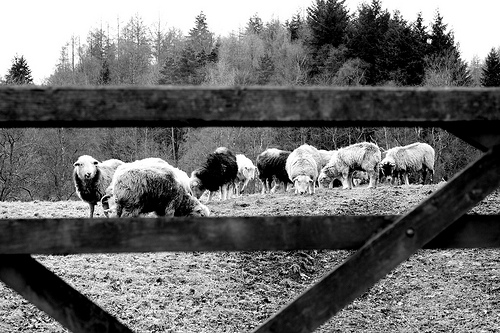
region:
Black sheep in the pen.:
[195, 147, 242, 199]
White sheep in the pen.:
[287, 144, 321, 199]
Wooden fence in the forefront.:
[2, 81, 494, 331]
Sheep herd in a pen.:
[39, 125, 437, 204]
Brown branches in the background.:
[3, 136, 69, 201]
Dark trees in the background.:
[302, 1, 457, 92]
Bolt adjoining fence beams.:
[401, 225, 411, 236]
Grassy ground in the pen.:
[1, 198, 496, 329]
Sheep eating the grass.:
[320, 135, 385, 190]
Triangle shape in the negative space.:
[26, 240, 358, 332]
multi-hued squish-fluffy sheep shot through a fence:
[68, 127, 446, 217]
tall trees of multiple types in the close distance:
[1, 0, 498, 202]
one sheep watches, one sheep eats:
[62, 150, 214, 213]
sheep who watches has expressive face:
[66, 151, 103, 185]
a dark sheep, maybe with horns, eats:
[184, 147, 244, 204]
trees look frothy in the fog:
[63, 27, 451, 160]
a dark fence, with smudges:
[1, 85, 497, 331]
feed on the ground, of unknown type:
[0, 183, 441, 331]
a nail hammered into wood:
[401, 220, 426, 242]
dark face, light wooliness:
[376, 158, 401, 186]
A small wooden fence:
[0, 85, 496, 332]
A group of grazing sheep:
[70, 140, 438, 216]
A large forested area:
[0, 0, 498, 199]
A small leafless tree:
[1, 133, 41, 198]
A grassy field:
[1, 183, 495, 328]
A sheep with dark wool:
[189, 152, 243, 198]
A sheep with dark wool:
[256, 152, 288, 192]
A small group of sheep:
[70, 150, 207, 220]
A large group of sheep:
[185, 140, 436, 195]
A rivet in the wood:
[405, 225, 415, 237]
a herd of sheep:
[69, 132, 459, 232]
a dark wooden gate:
[8, 70, 494, 321]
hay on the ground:
[243, 185, 384, 212]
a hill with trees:
[35, 0, 457, 183]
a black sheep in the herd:
[193, 143, 244, 195]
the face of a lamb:
[381, 158, 397, 188]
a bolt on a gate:
[386, 225, 422, 250]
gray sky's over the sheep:
[20, 0, 261, 53]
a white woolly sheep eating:
[283, 145, 319, 195]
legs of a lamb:
[339, 171, 356, 191]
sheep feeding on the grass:
[245, 138, 436, 195]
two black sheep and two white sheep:
[180, 135, 313, 206]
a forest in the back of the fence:
[4, 54, 262, 141]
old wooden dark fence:
[317, 72, 497, 274]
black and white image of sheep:
[56, 134, 216, 229]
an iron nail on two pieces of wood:
[374, 194, 456, 276]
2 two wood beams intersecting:
[346, 187, 485, 307]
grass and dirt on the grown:
[105, 262, 265, 315]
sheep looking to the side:
[66, 142, 126, 216]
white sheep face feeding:
[289, 169, 319, 201]